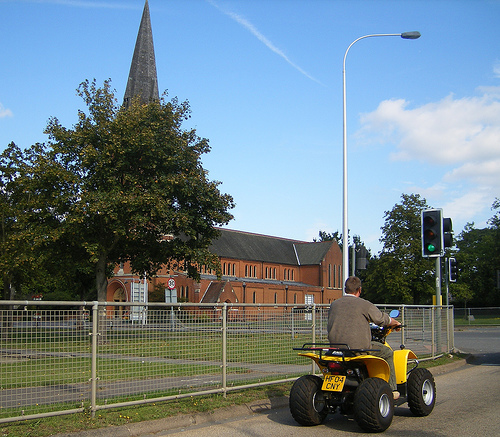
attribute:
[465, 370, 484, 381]
road — black paved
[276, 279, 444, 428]
vehicle — yellow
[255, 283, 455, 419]
vehicle — yellow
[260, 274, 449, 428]
vehicle — yellow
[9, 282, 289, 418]
fence — gray 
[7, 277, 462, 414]
fence — gray 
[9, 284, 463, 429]
fence — gray 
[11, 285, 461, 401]
fence — gray 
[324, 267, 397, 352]
man — gray shirt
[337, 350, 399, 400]
man — gray pants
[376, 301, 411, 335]
atv — mirror 